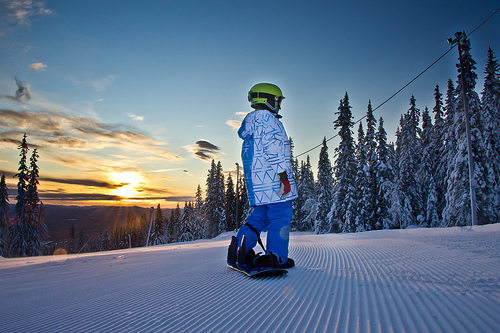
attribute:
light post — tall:
[445, 30, 479, 227]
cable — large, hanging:
[303, 32, 445, 159]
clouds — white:
[28, 98, 158, 156]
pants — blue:
[230, 201, 292, 266]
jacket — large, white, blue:
[231, 107, 306, 206]